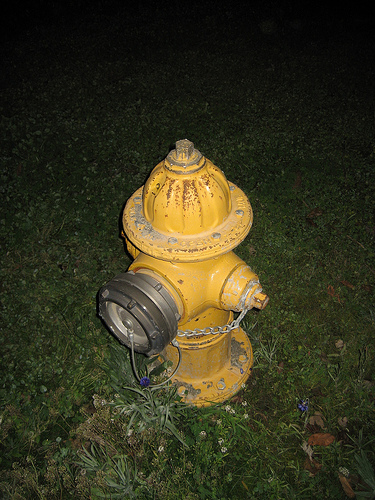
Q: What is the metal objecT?
A: Fire Hydrant.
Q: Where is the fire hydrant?
A: On the grass.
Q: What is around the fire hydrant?
A: Grass.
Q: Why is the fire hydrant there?
A: For the fire department.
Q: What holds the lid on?
A: Chain.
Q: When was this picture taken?
A: During the night.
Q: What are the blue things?
A: Flowers.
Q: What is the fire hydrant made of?
A: Metal.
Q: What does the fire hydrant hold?
A: Water.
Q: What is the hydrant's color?
A: Yellow.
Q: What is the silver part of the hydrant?
A: Security cap.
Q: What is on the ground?
A: Leaves.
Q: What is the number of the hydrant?
A: 1.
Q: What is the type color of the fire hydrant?
A: Yellow.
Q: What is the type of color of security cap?
A: Gray.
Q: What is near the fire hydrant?
A: Grass.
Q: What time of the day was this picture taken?
A: At night.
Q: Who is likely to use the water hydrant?
A: A fireman.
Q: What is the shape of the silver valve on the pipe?
A: Round.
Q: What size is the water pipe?
A: Small.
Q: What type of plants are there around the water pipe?
A: Weeds.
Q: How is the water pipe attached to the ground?
A: With bolts.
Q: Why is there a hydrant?
A: For fires.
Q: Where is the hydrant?
A: On the grass.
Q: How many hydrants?
A: 1.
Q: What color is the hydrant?
A: Yellow.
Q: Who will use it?
A: Firemen.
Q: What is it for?
A: To put fires out.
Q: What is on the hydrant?
A: Chain.